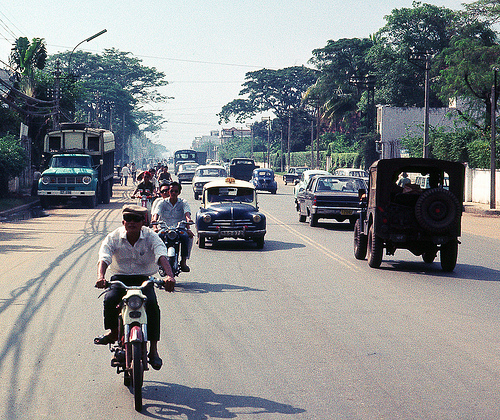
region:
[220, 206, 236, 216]
the car is blue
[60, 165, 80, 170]
the truck is teal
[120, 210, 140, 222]
he's wearing black sunglasses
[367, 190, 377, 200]
the jeep is brown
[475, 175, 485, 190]
the wall is white in color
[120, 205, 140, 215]
the hat is tan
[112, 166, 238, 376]
the traffic is coming forward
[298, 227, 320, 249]
the line is yellow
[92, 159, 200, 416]
Many people riding bicycles down a road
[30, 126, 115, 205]
Blue truck with a camper parked on a sidewalk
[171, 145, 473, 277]
Many older cars driving on a road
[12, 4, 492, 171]
Tall green trees along a road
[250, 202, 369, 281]
Yellow double line divider on a road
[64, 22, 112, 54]
Street lamp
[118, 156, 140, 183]
People standing on a sidewalk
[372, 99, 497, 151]
Old white building surrounded by trees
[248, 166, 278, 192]
Blue punch buggy car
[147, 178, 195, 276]
Two men riding on a bicycle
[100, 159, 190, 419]
Line of people riding motorized scooters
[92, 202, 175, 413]
Man on a motorized scooter in a hat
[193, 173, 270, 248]
Old-fashioned police car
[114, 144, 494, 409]
Street scene with traffic going both directions.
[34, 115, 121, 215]
Truck with a camper parked on the sidewalk.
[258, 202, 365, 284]
Double yellow do not pass center road line.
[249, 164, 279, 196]
A VW Bug from the 1960s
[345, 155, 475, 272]
Old-fashioned military style jeep on the road.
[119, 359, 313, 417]
The shadow of a man on a motorized scooter bike.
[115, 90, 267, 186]
The haze hanging over a city.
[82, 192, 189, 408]
person riding a bike on the street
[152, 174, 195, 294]
person riding a bike on the street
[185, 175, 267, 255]
car driving on the street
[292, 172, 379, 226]
car driving on the street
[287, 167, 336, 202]
car driving on the street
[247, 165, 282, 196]
car driving on the street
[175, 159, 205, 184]
car driving on the street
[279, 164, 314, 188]
car driving on the street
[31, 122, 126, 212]
truck parked on the side of the street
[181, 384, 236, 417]
shadow on the ground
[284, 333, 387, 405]
ground is grey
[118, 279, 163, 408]
a motorbike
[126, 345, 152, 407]
a tire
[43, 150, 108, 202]
a blue truck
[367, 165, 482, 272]
a jeep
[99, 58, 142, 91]
leaves on the tree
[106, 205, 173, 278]
man on the bike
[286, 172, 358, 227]
a car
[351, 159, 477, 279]
an old military jeep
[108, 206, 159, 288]
a person wearing a shirt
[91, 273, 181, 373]
a person wearing a pair of pants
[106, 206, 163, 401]
a person riding a motorbike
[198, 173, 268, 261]
a very old taxi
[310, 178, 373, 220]
the back of an old sedan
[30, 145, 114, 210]
the head of a green truck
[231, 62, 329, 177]
a very tall tree at the side of a road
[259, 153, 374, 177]
a long hedge by the road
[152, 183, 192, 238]
2 people riding a motorcycle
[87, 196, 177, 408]
man on motorcycle wearing a hat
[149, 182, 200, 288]
man on motorcycle wearing a white shirt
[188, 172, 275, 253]
blue and white colored car on street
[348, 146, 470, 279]
old brown antique looking car on street